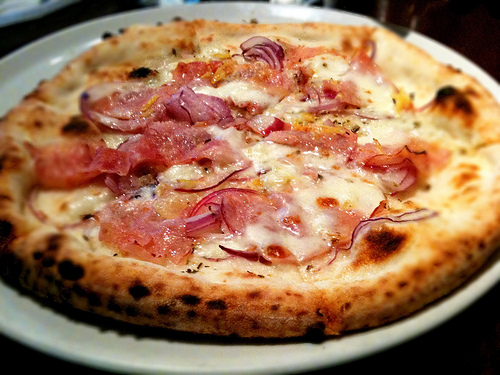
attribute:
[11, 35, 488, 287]
cheese — melted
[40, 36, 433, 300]
pizza — cooked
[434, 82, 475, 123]
crust spot — dark, burnt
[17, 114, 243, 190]
bacon — long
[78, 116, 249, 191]
bacon — pink, long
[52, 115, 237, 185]
meat — cooked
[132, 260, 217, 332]
crust — golden, brown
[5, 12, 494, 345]
pizza — small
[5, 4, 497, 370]
plate — white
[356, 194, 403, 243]
onion — red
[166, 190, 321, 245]
cheese — burnt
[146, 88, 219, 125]
ham — cooked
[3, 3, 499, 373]
tray — metal, silver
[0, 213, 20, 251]
spot — burnt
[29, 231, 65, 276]
spot — burnt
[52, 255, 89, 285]
spot — burnt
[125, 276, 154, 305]
spot — burnt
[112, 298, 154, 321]
spot — burnt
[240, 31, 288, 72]
onion clump — clumped